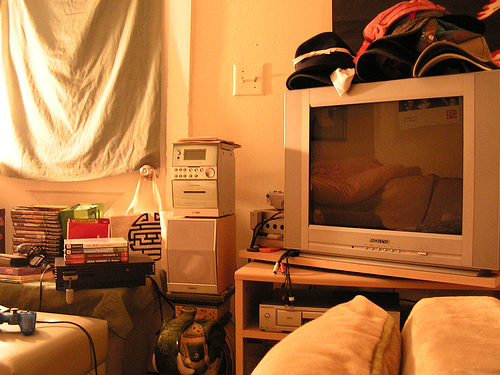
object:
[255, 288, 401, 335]
dvd player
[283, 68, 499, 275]
tv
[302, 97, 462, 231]
reflection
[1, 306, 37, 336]
controller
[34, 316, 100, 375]
cord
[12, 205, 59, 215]
video games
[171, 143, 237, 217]
stero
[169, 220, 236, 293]
speaker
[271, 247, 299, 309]
cord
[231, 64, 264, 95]
light switch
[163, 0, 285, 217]
wall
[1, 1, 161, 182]
sheet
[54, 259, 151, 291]
game system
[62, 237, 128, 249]
video games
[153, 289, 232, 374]
elephant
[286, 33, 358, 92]
hat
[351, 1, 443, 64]
hat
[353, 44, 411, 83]
hat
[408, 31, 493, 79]
hat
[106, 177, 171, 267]
bag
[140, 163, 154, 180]
door knob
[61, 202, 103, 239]
bag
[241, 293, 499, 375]
couch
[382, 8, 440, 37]
hat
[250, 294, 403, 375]
cushion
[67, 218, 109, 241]
bag